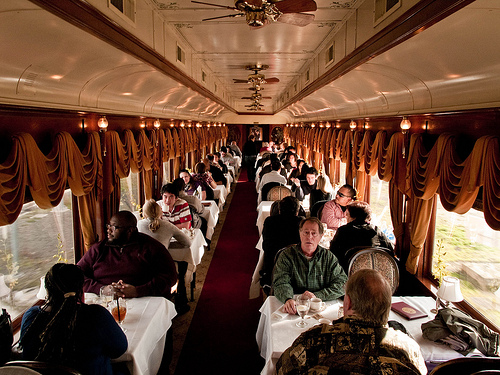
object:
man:
[75, 210, 180, 299]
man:
[272, 266, 428, 373]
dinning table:
[7, 294, 179, 374]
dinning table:
[253, 294, 494, 372]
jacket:
[75, 233, 180, 292]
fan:
[186, 0, 319, 34]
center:
[151, 3, 348, 114]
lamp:
[431, 273, 466, 316]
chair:
[343, 246, 401, 294]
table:
[255, 293, 493, 374]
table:
[254, 200, 310, 235]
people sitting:
[0, 135, 241, 373]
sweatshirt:
[70, 234, 180, 296]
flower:
[430, 235, 448, 279]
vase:
[428, 287, 443, 316]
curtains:
[284, 125, 499, 274]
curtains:
[0, 127, 227, 252]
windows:
[367, 164, 407, 251]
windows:
[118, 168, 146, 222]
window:
[2, 185, 76, 331]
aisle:
[159, 149, 266, 374]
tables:
[165, 226, 207, 271]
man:
[267, 216, 350, 310]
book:
[389, 300, 429, 322]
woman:
[18, 261, 127, 373]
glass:
[108, 290, 127, 334]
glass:
[290, 290, 310, 330]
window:
[427, 192, 497, 333]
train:
[0, 0, 498, 372]